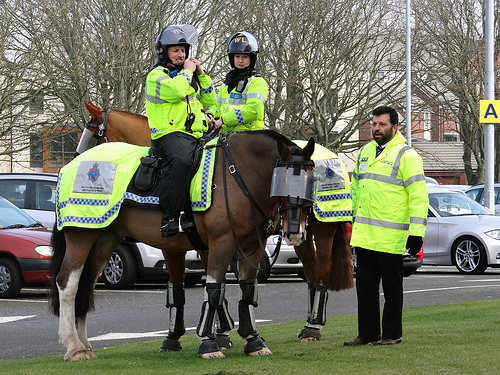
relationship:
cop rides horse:
[142, 20, 212, 239] [43, 131, 317, 360]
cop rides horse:
[212, 32, 268, 133] [78, 101, 350, 351]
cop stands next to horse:
[345, 106, 428, 346] [78, 101, 350, 351]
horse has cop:
[43, 131, 317, 360] [137, 22, 221, 239]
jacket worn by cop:
[144, 64, 220, 141] [137, 22, 221, 239]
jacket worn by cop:
[218, 68, 273, 130] [206, 27, 273, 132]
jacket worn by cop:
[342, 128, 429, 255] [332, 98, 434, 351]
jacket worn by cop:
[139, 64, 216, 134] [137, 22, 221, 239]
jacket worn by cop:
[342, 128, 429, 255] [205, 27, 277, 136]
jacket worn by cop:
[342, 134, 429, 254] [332, 98, 434, 351]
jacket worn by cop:
[144, 64, 220, 141] [135, 23, 215, 241]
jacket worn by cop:
[342, 128, 429, 255] [197, 21, 287, 133]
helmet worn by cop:
[155, 24, 197, 45] [137, 22, 221, 239]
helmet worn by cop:
[223, 31, 261, 55] [200, 25, 283, 130]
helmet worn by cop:
[155, 24, 197, 47] [147, 20, 222, 249]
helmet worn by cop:
[223, 31, 261, 55] [204, 26, 290, 135]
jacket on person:
[144, 64, 220, 141] [139, 20, 209, 246]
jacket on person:
[342, 128, 429, 255] [207, 28, 277, 128]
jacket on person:
[342, 128, 429, 255] [340, 97, 436, 351]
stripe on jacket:
[150, 72, 169, 100] [137, 61, 221, 140]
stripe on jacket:
[234, 108, 247, 122] [137, 61, 221, 140]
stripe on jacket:
[360, 167, 407, 189] [219, 69, 269, 129]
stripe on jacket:
[358, 203, 414, 233] [342, 134, 429, 254]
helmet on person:
[155, 24, 197, 47] [143, 18, 221, 235]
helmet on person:
[223, 31, 261, 55] [201, 23, 281, 134]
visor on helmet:
[159, 22, 198, 43] [156, 27, 203, 50]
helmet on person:
[155, 24, 197, 47] [135, 17, 214, 239]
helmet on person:
[223, 27, 261, 53] [208, 22, 278, 135]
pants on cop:
[155, 135, 204, 212] [142, 22, 217, 239]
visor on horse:
[72, 124, 111, 153] [51, 98, 160, 154]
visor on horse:
[268, 163, 320, 203] [43, 131, 317, 360]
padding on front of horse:
[195, 270, 266, 335] [43, 131, 317, 360]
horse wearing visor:
[43, 129, 318, 360] [272, 160, 334, 205]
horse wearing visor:
[52, 97, 166, 164] [67, 124, 112, 151]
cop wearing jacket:
[142, 22, 217, 239] [144, 64, 220, 141]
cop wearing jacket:
[340, 105, 430, 347] [342, 128, 429, 255]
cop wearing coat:
[142, 22, 217, 239] [140, 60, 211, 145]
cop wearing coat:
[340, 105, 430, 347] [347, 135, 432, 272]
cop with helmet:
[142, 22, 217, 239] [152, 20, 195, 50]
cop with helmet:
[204, 30, 271, 134] [221, 30, 270, 55]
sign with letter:
[469, 90, 492, 119] [482, 103, 492, 108]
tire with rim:
[444, 234, 491, 283] [459, 240, 479, 270]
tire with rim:
[98, 235, 133, 289] [104, 250, 123, 279]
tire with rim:
[4, 251, 22, 304] [0, 267, 10, 291]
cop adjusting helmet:
[142, 22, 217, 239] [158, 22, 188, 47]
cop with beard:
[340, 105, 430, 347] [371, 128, 396, 141]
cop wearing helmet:
[204, 30, 271, 134] [222, 28, 263, 53]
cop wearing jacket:
[204, 30, 271, 134] [205, 68, 270, 135]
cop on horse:
[142, 22, 217, 239] [43, 131, 317, 360]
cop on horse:
[204, 30, 271, 134] [78, 101, 350, 351]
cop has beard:
[340, 105, 430, 347] [371, 130, 391, 144]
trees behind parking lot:
[1, 4, 493, 182] [0, 244, 496, 358]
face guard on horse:
[271, 164, 309, 196] [43, 131, 317, 360]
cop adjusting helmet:
[142, 22, 217, 239] [45, 131, 308, 361]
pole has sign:
[481, 5, 495, 205] [478, 98, 498, 125]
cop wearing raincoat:
[340, 105, 430, 347] [349, 138, 429, 256]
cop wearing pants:
[340, 105, 430, 347] [354, 249, 404, 339]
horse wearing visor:
[43, 131, 317, 360] [274, 162, 308, 202]